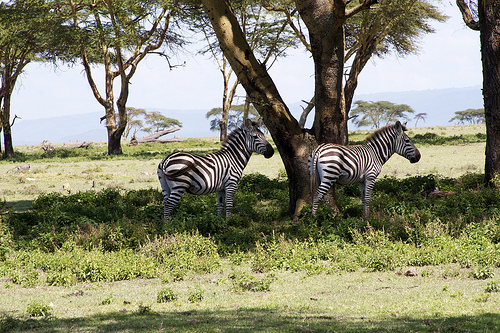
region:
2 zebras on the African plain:
[11, 13, 485, 322]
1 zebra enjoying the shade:
[141, 118, 276, 228]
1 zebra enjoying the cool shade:
[308, 119, 423, 228]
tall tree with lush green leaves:
[58, 0, 180, 162]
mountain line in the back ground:
[1, 89, 479, 145]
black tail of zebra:
[165, 160, 201, 179]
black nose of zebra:
[262, 142, 276, 159]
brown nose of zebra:
[406, 148, 420, 160]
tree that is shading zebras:
[200, 5, 438, 208]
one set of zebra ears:
[240, 113, 262, 133]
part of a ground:
[336, 266, 364, 306]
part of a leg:
[303, 188, 323, 223]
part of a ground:
[352, 277, 373, 314]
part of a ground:
[324, 259, 351, 289]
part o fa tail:
[300, 152, 318, 185]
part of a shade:
[364, 309, 374, 321]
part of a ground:
[264, 252, 307, 329]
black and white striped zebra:
[141, 105, 268, 224]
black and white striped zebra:
[299, 108, 415, 200]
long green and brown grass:
[14, 234, 93, 283]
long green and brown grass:
[14, 193, 72, 223]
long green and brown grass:
[45, 164, 105, 190]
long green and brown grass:
[103, 159, 129, 174]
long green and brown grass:
[104, 206, 142, 264]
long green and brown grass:
[156, 233, 210, 289]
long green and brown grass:
[215, 226, 283, 285]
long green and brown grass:
[273, 226, 335, 272]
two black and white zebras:
[152, 100, 435, 244]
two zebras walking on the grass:
[138, 69, 433, 248]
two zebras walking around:
[147, 99, 434, 244]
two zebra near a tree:
[136, 95, 433, 257]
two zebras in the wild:
[8, 4, 495, 320]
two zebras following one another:
[16, 4, 493, 310]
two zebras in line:
[88, 86, 458, 273]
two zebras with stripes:
[38, 13, 485, 310]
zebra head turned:
[136, 100, 283, 241]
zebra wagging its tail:
[131, 106, 279, 240]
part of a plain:
[292, 217, 308, 230]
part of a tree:
[280, 112, 297, 132]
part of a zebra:
[343, 161, 362, 173]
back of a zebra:
[181, 162, 194, 183]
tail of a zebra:
[296, 157, 318, 204]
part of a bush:
[413, 23, 423, 28]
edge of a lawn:
[262, 257, 282, 262]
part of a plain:
[73, 223, 87, 239]